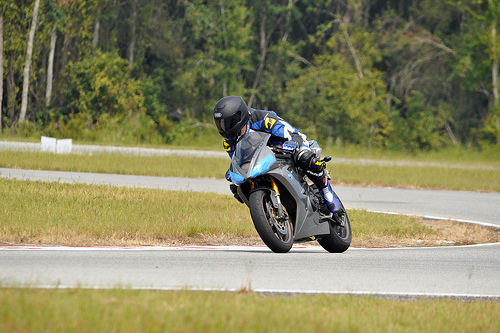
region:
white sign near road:
[40, 133, 73, 157]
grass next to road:
[3, 176, 425, 250]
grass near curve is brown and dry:
[422, 215, 498, 255]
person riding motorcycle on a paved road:
[213, 94, 355, 253]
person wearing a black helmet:
[212, 95, 249, 139]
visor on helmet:
[215, 114, 242, 131]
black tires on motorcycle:
[249, 193, 295, 252]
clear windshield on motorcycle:
[230, 132, 270, 177]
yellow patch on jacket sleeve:
[264, 117, 276, 130]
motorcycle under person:
[225, 134, 356, 256]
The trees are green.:
[259, 23, 494, 97]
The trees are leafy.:
[265, 23, 492, 144]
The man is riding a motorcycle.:
[179, 68, 379, 266]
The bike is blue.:
[210, 112, 371, 270]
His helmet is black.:
[210, 81, 342, 173]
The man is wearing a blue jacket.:
[195, 45, 335, 190]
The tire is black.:
[230, 175, 324, 259]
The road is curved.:
[29, 132, 499, 329]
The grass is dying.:
[29, 178, 216, 226]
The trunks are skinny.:
[25, 43, 213, 107]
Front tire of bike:
[231, 185, 298, 252]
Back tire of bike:
[315, 207, 359, 254]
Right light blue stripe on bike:
[255, 150, 276, 175]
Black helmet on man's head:
[205, 95, 250, 131]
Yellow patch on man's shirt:
[257, 112, 274, 127]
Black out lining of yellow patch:
[271, 111, 276, 122]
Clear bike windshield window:
[230, 137, 255, 162]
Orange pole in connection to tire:
[267, 172, 279, 197]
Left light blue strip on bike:
[220, 166, 250, 182]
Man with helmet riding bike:
[196, 81, 371, 265]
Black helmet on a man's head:
[212, 97, 249, 132]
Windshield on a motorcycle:
[230, 130, 260, 165]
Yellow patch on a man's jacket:
[262, 112, 277, 132]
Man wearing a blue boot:
[320, 177, 342, 214]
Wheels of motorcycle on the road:
[228, 173, 360, 263]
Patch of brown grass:
[431, 215, 491, 242]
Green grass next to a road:
[13, 180, 213, 227]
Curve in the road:
[378, 191, 497, 302]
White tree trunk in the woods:
[22, 0, 49, 122]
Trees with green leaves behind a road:
[106, 2, 485, 91]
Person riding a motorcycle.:
[178, 82, 373, 260]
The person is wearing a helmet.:
[198, 90, 257, 133]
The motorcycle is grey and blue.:
[208, 142, 330, 243]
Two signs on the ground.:
[23, 131, 85, 156]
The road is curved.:
[3, 134, 499, 317]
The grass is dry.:
[36, 178, 178, 241]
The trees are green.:
[183, 17, 305, 79]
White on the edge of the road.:
[413, 207, 498, 241]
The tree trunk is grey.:
[15, 4, 40, 130]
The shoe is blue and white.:
[313, 181, 348, 223]